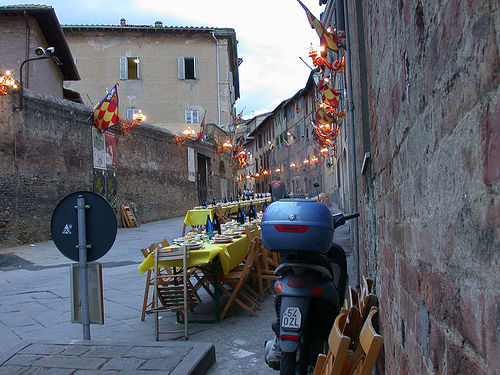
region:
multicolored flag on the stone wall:
[80, 81, 125, 134]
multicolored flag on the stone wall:
[192, 105, 208, 142]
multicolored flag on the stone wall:
[293, 0, 346, 53]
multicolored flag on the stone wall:
[312, 66, 346, 108]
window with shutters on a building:
[177, 52, 202, 84]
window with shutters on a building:
[117, 53, 142, 80]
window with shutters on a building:
[183, 105, 197, 126]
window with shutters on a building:
[127, 105, 139, 121]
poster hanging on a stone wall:
[87, 127, 120, 177]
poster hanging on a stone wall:
[183, 143, 198, 185]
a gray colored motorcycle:
[257, 198, 359, 373]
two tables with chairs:
[138, 190, 276, 339]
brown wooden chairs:
[216, 236, 286, 323]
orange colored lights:
[0, 55, 336, 181]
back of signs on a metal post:
[51, 188, 118, 343]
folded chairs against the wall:
[310, 269, 382, 373]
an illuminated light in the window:
[118, 55, 141, 81]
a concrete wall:
[0, 79, 242, 251]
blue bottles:
[202, 196, 268, 237]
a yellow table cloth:
[138, 209, 265, 281]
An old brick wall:
[424, 185, 477, 374]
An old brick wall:
[365, 110, 445, 360]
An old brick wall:
[147, 131, 191, 208]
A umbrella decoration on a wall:
[81, 80, 123, 142]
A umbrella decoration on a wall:
[122, 101, 148, 133]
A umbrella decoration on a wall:
[169, 115, 195, 150]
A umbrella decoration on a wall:
[233, 147, 261, 175]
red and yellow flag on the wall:
[91, 88, 128, 138]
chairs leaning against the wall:
[298, 308, 390, 373]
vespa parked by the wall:
[250, 182, 358, 359]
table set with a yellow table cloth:
[147, 205, 253, 307]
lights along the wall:
[238, 153, 334, 178]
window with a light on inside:
[115, 43, 152, 89]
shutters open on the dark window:
[172, 54, 204, 79]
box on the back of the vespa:
[261, 198, 343, 250]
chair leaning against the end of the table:
[148, 253, 195, 327]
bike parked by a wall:
[256, 184, 350, 368]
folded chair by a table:
[147, 243, 197, 345]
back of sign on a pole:
[48, 179, 129, 346]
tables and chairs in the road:
[132, 197, 259, 328]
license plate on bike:
[276, 292, 310, 347]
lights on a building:
[236, 160, 336, 184]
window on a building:
[173, 53, 208, 93]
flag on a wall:
[83, 77, 133, 142]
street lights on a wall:
[16, 35, 68, 101]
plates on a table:
[209, 232, 233, 246]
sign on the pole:
[51, 202, 111, 264]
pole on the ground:
[50, 325, 106, 337]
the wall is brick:
[392, 203, 463, 285]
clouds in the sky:
[166, 9, 193, 22]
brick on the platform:
[128, 343, 174, 360]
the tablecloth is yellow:
[222, 249, 233, 259]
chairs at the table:
[217, 244, 271, 302]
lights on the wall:
[307, 91, 340, 145]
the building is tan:
[156, 84, 177, 94]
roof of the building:
[175, 25, 197, 34]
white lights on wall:
[0, 68, 18, 93]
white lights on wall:
[127, 108, 147, 125]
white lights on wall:
[181, 122, 198, 137]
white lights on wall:
[221, 137, 234, 149]